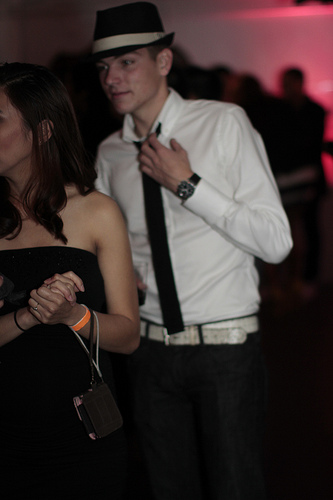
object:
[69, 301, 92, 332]
bracelet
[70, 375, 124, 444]
cellphone case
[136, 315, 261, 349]
belt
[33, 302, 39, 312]
ring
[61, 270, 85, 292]
finger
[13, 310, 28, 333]
rubber band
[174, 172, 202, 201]
watch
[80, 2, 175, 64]
hat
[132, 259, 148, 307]
cup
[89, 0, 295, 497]
boy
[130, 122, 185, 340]
tie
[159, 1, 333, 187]
pink light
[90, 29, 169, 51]
ribbon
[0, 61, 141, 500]
girl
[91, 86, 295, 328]
shirt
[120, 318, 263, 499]
pants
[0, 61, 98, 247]
hair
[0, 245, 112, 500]
black